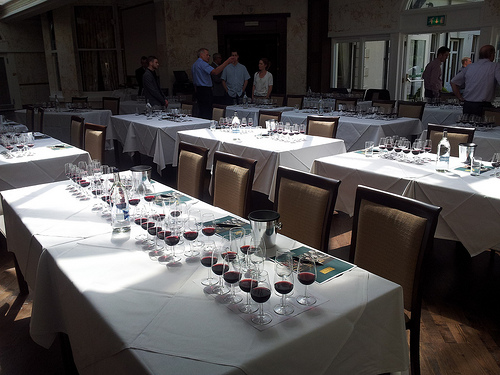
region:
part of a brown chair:
[355, 184, 440, 373]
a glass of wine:
[295, 253, 322, 308]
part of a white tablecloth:
[315, 149, 498, 251]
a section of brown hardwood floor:
[425, 295, 497, 374]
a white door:
[401, 35, 431, 99]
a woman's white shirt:
[249, 67, 273, 97]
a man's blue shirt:
[190, 55, 217, 87]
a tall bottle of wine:
[437, 123, 452, 168]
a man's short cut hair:
[434, 45, 449, 60]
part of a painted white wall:
[462, 36, 470, 54]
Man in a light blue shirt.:
[221, 52, 247, 106]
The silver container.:
[249, 215, 286, 250]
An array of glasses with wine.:
[213, 250, 322, 321]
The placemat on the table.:
[282, 245, 355, 286]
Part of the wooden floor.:
[426, 310, 483, 370]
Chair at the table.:
[170, 135, 205, 193]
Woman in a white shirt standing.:
[254, 58, 276, 98]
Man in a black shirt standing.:
[137, 55, 172, 112]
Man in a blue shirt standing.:
[192, 50, 216, 107]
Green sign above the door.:
[426, 13, 450, 30]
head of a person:
[193, 42, 221, 60]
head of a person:
[132, 35, 180, 80]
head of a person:
[230, 41, 260, 73]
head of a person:
[253, 56, 287, 73]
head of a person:
[423, 45, 465, 69]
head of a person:
[475, 35, 493, 65]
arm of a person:
[445, 68, 480, 108]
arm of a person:
[409, 55, 433, 99]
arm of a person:
[210, 55, 244, 73]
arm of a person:
[147, 81, 174, 106]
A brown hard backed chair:
[348, 184, 442, 374]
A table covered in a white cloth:
[2, 168, 412, 373]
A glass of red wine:
[297, 256, 317, 306]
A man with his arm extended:
[191, 46, 240, 120]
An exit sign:
[424, 13, 445, 24]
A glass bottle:
[436, 128, 451, 170]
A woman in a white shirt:
[252, 58, 276, 103]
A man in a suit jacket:
[143, 56, 170, 110]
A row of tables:
[12, 92, 499, 259]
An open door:
[402, 31, 432, 101]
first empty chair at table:
[368, 208, 395, 247]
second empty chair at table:
[287, 181, 308, 211]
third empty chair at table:
[223, 167, 239, 194]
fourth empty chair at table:
[175, 148, 198, 180]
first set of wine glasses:
[211, 241, 287, 306]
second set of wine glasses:
[141, 204, 203, 253]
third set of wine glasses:
[93, 172, 140, 211]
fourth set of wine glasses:
[64, 160, 109, 194]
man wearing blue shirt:
[230, 72, 243, 89]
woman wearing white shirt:
[258, 80, 269, 90]